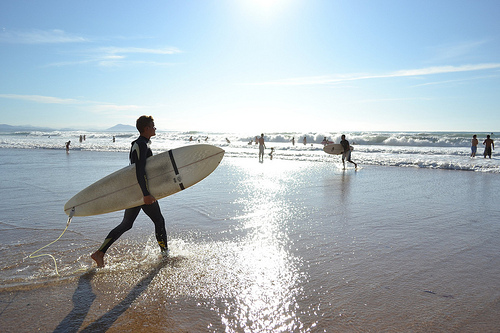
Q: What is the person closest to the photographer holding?
A: Surfboard.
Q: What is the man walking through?
A: Water.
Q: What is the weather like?
A: Sunny.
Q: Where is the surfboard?
A: In the man's arm.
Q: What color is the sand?
A: Brown.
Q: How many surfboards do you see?
A: 2.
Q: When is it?
A: Daytime.